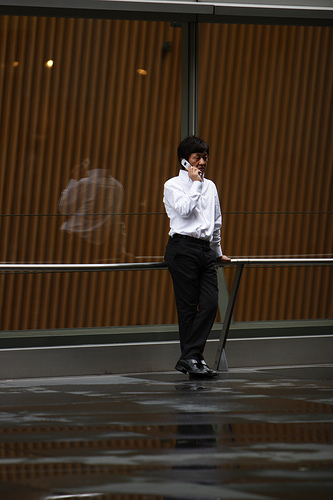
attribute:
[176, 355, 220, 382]
shoes — black, shiny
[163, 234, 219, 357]
pants — black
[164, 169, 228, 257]
shirt — white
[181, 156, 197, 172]
phone — white, old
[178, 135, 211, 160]
hair — brown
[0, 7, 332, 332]
wall — brown